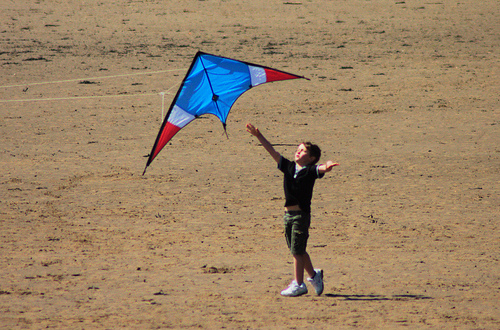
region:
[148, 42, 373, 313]
The young boy is flying a kite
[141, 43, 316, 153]
The kite is red, white, and blue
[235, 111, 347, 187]
The boy has his hands in the air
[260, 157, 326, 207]
The boy is wearing a black shirt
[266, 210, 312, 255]
The boy is wearing green pants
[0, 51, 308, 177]
kite with white strings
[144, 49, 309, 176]
red, white and blue kite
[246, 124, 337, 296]
boy with raised hand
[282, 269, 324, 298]
white sneakers on two feet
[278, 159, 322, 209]
short sleeved dark shirt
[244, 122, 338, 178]
two outstretched arms of boy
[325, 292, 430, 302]
shadow of boy on ground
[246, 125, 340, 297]
standing boy in shorts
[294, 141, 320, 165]
short dark hair on head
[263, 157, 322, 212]
boy wearing a black shirt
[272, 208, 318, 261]
boy wearing green shorts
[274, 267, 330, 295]
boy wearing white sneakers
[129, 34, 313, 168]
red white and blue kite in the sky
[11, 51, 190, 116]
string attached to a kite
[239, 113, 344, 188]
boy with his arms open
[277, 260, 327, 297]
boy wearing white tennis shoes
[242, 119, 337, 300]
boy tossing kite into the sky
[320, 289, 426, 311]
shadow of the boy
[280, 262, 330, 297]
white shoes the boy is wearing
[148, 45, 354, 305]
A child flying a kite.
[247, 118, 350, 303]
A child on the beach.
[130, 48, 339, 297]
A young boy playing with a kite.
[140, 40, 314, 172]
A blue, white and red kite.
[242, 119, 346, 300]
The boy is holding the string.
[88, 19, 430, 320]
The boy is playing on a beach.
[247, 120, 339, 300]
The boy wears white sneakers.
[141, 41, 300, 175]
The kite is in the air.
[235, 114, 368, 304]
The boy has his arms in the air.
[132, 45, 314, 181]
blue, white and red kite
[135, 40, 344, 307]
boy flying kite in dirt field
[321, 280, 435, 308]
black shadow of boy on dirt ground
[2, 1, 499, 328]
brown field of dirt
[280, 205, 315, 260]
pair of green shorts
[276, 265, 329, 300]
pair of white sneakers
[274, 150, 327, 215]
black short sleeve shirt with grey accents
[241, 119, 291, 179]
outstretched hand and arm of boy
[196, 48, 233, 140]
black line down middle of triangular shaped kite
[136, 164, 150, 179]
black spoke tip of triangular kite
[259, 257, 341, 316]
feet of the kid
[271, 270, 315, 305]
shoe on the foot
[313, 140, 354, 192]
arm of the kid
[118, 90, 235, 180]
blue, red and white kite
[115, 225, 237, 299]
dirt on the ground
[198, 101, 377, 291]
kid under a kite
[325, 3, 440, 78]
dirt in the distance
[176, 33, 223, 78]
top part of kite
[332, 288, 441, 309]
shadow behind the boy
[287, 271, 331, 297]
the boy's white shoes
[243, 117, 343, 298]
the boy flying the kite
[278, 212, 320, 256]
the boy's green shorts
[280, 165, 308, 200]
the boy's black shirt